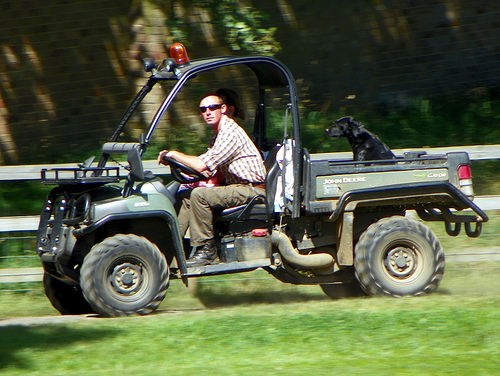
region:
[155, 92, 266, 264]
man wearing a plaid shirt and sunglasses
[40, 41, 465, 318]
a man riding a golf cart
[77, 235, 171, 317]
golf cart's front left tire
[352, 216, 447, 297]
golf cart's left rear wheel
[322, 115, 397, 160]
dog sitting in a golf cart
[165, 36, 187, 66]
red light on a golf cart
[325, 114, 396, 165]
A black labrador retriever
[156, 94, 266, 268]
A man wearing black boots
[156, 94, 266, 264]
A man wearing a plaid shirt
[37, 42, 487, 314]
A man driving a John Deere off-road vehicle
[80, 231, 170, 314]
The tire of an off-road vehicle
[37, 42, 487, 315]
A black dog riding in an off-road vehicle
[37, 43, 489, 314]
A dog riding in the back of an off-road vehicle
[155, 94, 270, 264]
A man leaning over a steering wheel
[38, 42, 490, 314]
Two people and a dog in an off-road vehicle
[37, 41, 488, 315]
the green vehicle in motion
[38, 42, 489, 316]
the wheels on the green vehicle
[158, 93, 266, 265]
the man is sitting down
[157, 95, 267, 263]
the man in the driver's seat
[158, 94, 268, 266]
the man with arms on the steering wheel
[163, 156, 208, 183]
the steering wheel is black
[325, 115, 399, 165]
the sitting black dog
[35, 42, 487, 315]
the light on the top of the vehicle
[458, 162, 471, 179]
the red tail light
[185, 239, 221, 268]
the black leather boot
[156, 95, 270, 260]
Man sitting in a truck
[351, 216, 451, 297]
Back tire on utility truck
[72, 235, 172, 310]
Front tire on utility truck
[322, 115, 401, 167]
Dog riding in a truck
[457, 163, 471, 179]
Red tail light on a truck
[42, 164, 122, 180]
Black shelf on front of truck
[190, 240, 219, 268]
Black boot on a man's foot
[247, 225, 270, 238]
Red gas tank cover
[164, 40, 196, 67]
Orange light on top of a truck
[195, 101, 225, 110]
Sunglasses on man's face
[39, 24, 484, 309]
a green John Deere vehicle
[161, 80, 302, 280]
man in sun glasses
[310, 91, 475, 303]
a black dog in the back of a vehicle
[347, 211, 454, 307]
Tire of a vehicle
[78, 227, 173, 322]
Tire of a vehicle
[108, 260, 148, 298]
Rim of a tire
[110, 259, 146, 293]
Rim of a black tire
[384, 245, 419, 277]
Rim of a tire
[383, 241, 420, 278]
Rim of a black tire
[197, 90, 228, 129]
Head of a man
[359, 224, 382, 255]
Traction on a tire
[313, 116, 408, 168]
black colored dog in the back of vehicle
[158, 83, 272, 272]
man with sunglasses in the vehicle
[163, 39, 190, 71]
red light on vehicle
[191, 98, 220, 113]
sunglasses of the man sitting down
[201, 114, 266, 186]
red plaid shirt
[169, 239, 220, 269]
left shoe of the man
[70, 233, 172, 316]
front tire of the vehicle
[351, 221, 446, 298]
back tire of the vehicle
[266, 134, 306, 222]
white colored jacket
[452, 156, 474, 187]
red colored rear head light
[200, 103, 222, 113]
the man is wearing sunglasses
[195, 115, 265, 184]
the man is wearing a long sleeve shirt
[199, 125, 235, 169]
the sleeve is rolled up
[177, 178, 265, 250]
the man is wearing long pants